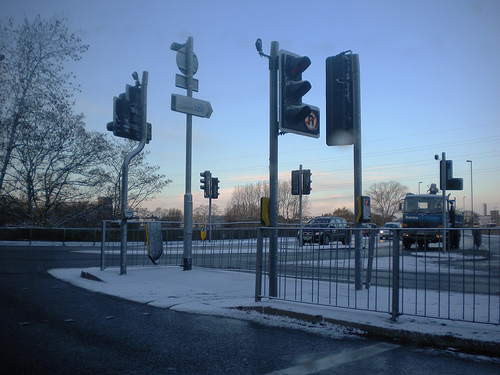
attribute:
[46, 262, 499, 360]
snow — white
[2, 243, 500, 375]
ground — wet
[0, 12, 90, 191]
tree — bare, tall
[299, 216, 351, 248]
car — stopped, black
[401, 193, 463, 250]
truck — blue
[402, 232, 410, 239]
light — on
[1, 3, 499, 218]
sky — blue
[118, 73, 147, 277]
pole — curved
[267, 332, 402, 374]
line — white, painted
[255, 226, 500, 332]
railing — metal, silver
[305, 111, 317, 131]
circle — round, white, red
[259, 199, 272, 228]
traffic sign — black, yellow